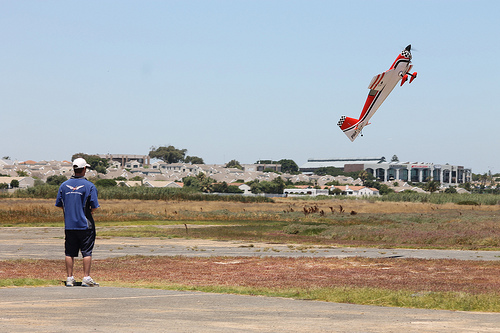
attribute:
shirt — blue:
[53, 177, 100, 230]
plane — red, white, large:
[334, 38, 426, 138]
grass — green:
[156, 279, 498, 318]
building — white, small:
[281, 182, 332, 201]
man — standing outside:
[15, 140, 147, 290]